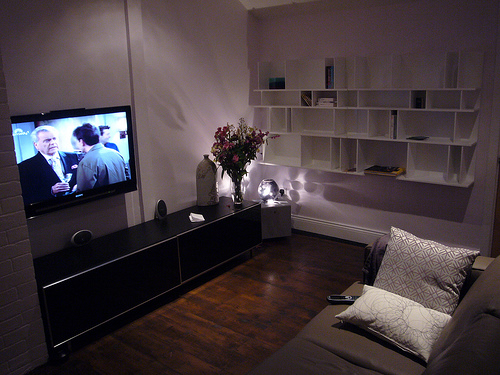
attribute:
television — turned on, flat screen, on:
[10, 102, 138, 218]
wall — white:
[1, 0, 248, 260]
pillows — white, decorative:
[336, 225, 482, 364]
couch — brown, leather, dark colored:
[229, 223, 498, 372]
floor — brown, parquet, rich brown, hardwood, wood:
[28, 229, 367, 374]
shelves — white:
[249, 50, 483, 186]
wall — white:
[247, 1, 499, 257]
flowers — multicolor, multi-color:
[208, 117, 279, 206]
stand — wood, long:
[34, 193, 262, 357]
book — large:
[364, 164, 403, 177]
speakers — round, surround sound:
[69, 197, 168, 248]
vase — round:
[256, 176, 279, 205]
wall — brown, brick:
[0, 57, 50, 374]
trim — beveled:
[124, 0, 159, 222]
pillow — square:
[336, 284, 453, 364]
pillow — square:
[372, 223, 480, 317]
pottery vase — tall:
[192, 152, 218, 208]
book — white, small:
[186, 208, 206, 223]